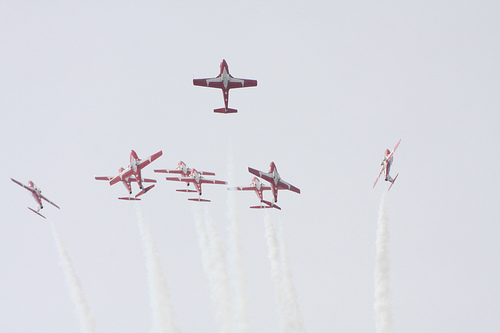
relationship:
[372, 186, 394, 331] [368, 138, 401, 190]
smoke coming from airplane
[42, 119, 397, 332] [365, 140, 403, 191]
smoke trails are coming from planes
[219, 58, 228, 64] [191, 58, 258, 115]
prop belongs to airplane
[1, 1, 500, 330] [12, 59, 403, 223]
sky contains nine planes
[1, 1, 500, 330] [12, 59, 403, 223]
sky contains jet planes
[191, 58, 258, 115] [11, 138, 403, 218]
plane over eight planes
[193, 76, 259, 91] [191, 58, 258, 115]
wings belong to jet plane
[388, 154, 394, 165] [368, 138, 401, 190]
cockpit belongs to jet plane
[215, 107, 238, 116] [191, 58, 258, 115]
stabilizer belongs to jet plane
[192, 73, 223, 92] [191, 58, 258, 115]
side wing belongs to airplane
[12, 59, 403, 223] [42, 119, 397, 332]
planes are leaving white trails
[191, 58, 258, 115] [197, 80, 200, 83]
plane in front red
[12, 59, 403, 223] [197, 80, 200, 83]
planes are colored red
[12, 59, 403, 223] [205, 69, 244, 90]
planes have white accents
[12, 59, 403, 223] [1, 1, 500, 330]
planes are in sky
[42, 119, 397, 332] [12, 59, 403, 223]
smoke trails come from airplanes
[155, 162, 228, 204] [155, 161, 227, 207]
two planes performing trick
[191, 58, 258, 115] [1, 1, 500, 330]
plane up in sky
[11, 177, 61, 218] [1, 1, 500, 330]
plane up in sky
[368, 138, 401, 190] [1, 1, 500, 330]
plane up in sky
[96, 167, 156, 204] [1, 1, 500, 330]
plane up in sky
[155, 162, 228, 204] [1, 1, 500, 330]
plane up in sky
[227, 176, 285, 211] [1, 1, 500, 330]
plane up in sky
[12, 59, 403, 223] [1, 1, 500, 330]
planes are up in sky